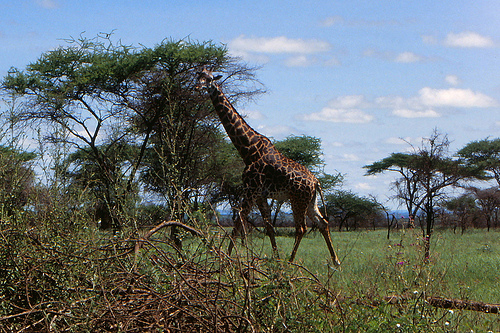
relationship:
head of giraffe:
[194, 68, 223, 92] [194, 67, 343, 271]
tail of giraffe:
[315, 180, 327, 222] [194, 67, 343, 271]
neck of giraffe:
[210, 84, 260, 165] [194, 67, 343, 271]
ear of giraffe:
[212, 72, 224, 81] [194, 67, 343, 271]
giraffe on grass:
[194, 67, 343, 271] [150, 229, 497, 325]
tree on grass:
[1, 37, 228, 233] [150, 229, 497, 325]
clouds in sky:
[302, 87, 496, 122] [0, 2, 498, 198]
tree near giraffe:
[1, 37, 228, 233] [194, 67, 343, 271]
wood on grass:
[384, 293, 499, 316] [150, 229, 497, 325]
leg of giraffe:
[224, 189, 266, 268] [194, 67, 343, 271]